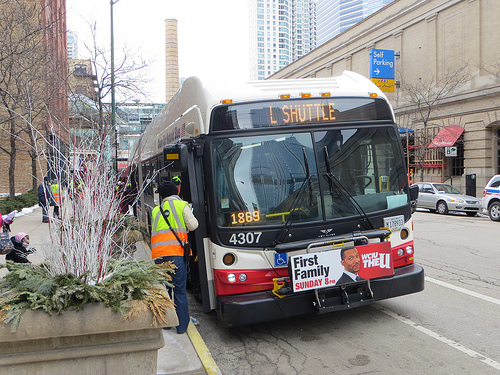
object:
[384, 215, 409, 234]
licence plate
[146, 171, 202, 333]
person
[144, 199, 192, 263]
vest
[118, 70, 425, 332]
bus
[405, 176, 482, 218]
car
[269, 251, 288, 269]
sign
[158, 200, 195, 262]
bag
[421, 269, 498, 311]
white line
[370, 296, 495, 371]
white line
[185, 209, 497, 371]
street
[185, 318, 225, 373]
curb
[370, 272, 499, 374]
two whitelines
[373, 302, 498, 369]
stripe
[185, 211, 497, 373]
road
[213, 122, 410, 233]
window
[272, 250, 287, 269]
handicapped sign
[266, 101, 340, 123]
light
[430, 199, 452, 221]
tire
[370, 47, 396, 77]
sign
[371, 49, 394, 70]
letter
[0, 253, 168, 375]
planter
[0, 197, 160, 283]
sidewalk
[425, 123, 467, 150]
awning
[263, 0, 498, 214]
building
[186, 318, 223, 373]
yellow paint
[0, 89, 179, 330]
plants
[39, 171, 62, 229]
people